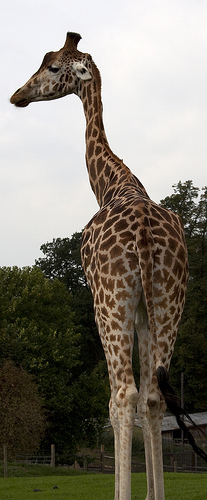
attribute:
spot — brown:
[93, 144, 100, 154]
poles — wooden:
[1, 443, 55, 475]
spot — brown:
[87, 158, 97, 181]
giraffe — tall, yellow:
[8, 31, 191, 498]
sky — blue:
[114, 21, 197, 104]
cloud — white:
[10, 156, 77, 178]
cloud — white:
[16, 186, 86, 206]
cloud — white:
[95, 0, 205, 82]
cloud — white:
[137, 97, 202, 149]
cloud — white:
[156, 151, 205, 169]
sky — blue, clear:
[0, 0, 205, 273]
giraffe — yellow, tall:
[45, 53, 104, 123]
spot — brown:
[86, 119, 96, 136]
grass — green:
[52, 474, 103, 498]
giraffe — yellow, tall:
[28, 30, 157, 211]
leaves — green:
[42, 323, 73, 357]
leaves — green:
[191, 317, 201, 336]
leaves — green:
[17, 276, 32, 286]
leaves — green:
[57, 252, 72, 280]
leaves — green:
[179, 185, 196, 195]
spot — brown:
[94, 156, 106, 174]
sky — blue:
[1, 1, 206, 237]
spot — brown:
[82, 105, 96, 114]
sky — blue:
[37, 204, 60, 223]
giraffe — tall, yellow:
[13, 32, 110, 133]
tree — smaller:
[1, 357, 44, 467]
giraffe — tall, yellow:
[17, 30, 185, 388]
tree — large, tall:
[7, 232, 82, 364]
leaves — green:
[3, 265, 79, 364]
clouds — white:
[112, 95, 126, 111]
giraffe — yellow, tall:
[3, 2, 203, 498]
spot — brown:
[51, 79, 56, 85]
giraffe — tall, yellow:
[14, 34, 186, 295]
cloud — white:
[19, 156, 89, 173]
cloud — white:
[21, 182, 77, 209]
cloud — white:
[10, 207, 26, 237]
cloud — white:
[8, 146, 55, 183]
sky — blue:
[3, 3, 195, 133]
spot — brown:
[151, 266, 176, 293]